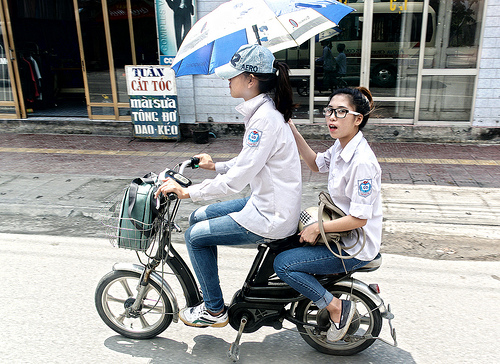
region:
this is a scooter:
[83, 151, 403, 351]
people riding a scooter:
[78, 25, 417, 362]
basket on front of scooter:
[95, 192, 176, 265]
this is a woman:
[283, 72, 385, 339]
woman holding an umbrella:
[125, 0, 411, 345]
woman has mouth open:
[315, 78, 374, 145]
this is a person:
[147, 38, 302, 333]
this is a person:
[265, 83, 388, 356]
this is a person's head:
[317, 85, 374, 142]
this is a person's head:
[210, 38, 300, 120]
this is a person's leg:
[172, 200, 287, 330]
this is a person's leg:
[271, 245, 387, 321]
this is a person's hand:
[154, 113, 278, 200]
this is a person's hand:
[299, 156, 380, 243]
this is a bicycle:
[87, 140, 406, 362]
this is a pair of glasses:
[312, 100, 368, 122]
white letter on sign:
[127, 88, 142, 108]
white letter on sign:
[134, 111, 156, 126]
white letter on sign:
[131, 125, 149, 140]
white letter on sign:
[155, 91, 176, 112]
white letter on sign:
[160, 105, 171, 122]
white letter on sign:
[165, 121, 177, 143]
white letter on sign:
[151, 116, 163, 138]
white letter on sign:
[150, 112, 155, 126]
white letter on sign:
[152, 122, 164, 134]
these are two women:
[42, 11, 416, 291]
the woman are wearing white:
[170, 64, 438, 306]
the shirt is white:
[224, 123, 328, 263]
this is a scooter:
[77, 187, 284, 362]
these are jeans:
[158, 185, 339, 332]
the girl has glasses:
[302, 84, 396, 138]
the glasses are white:
[314, 84, 371, 129]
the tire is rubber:
[82, 245, 174, 336]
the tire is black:
[51, 220, 186, 358]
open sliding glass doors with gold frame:
[1, 1, 156, 121]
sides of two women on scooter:
[95, 42, 383, 354]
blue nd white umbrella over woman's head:
[174, 1, 354, 101]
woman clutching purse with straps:
[276, 87, 382, 340]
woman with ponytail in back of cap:
[180, 42, 300, 326]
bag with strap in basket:
[105, 171, 163, 250]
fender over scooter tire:
[95, 260, 178, 338]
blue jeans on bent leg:
[274, 242, 372, 341]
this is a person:
[294, 83, 390, 330]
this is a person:
[174, 35, 300, 345]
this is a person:
[320, 28, 355, 103]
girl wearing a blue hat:
[213, 43, 286, 78]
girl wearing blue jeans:
[183, 188, 255, 306]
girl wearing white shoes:
[170, 294, 231, 330]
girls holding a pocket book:
[303, 192, 340, 254]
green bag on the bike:
[113, 165, 160, 242]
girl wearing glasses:
[316, 103, 372, 125]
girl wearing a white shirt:
[325, 129, 380, 259]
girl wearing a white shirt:
[201, 95, 307, 237]